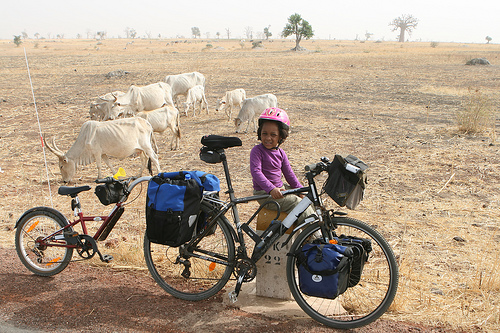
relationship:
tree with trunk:
[277, 4, 321, 55] [290, 41, 313, 58]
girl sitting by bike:
[242, 105, 353, 258] [7, 129, 401, 330]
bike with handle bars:
[7, 129, 401, 330] [310, 149, 353, 184]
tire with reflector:
[278, 217, 405, 328] [320, 237, 341, 247]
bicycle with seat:
[143, 118, 405, 332] [192, 129, 246, 168]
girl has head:
[242, 105, 353, 258] [249, 115, 296, 150]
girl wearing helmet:
[242, 105, 353, 258] [254, 103, 298, 133]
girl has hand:
[242, 105, 353, 258] [265, 189, 284, 199]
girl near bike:
[242, 105, 353, 258] [7, 129, 401, 330]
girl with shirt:
[242, 105, 353, 258] [242, 144, 309, 189]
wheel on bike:
[9, 200, 81, 278] [7, 129, 401, 330]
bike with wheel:
[7, 129, 401, 330] [9, 200, 81, 278]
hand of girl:
[265, 189, 284, 199] [242, 105, 353, 258]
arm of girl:
[246, 145, 277, 195] [242, 105, 353, 258]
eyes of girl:
[256, 130, 281, 139] [242, 105, 353, 258]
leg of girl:
[253, 187, 322, 247] [242, 105, 353, 258]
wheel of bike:
[9, 200, 81, 278] [7, 129, 401, 330]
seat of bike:
[192, 129, 246, 168] [7, 129, 401, 330]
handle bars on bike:
[310, 149, 353, 184] [7, 129, 401, 330]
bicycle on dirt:
[143, 118, 405, 332] [1, 240, 499, 325]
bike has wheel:
[7, 129, 401, 330] [9, 200, 81, 278]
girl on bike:
[242, 105, 353, 258] [7, 129, 401, 330]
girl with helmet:
[242, 105, 353, 258] [254, 103, 298, 133]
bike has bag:
[7, 129, 401, 330] [297, 234, 353, 300]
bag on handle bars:
[297, 234, 353, 300] [310, 149, 353, 184]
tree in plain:
[277, 4, 321, 55] [3, 38, 499, 222]